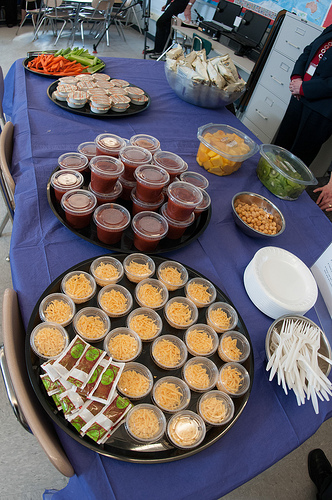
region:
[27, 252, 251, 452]
cheese cups on a tray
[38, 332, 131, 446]
sauce packets on the tray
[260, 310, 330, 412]
forks in a bowl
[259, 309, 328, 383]
the bowl is metal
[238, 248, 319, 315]
a stack of styrofoam plates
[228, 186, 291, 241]
chickpeas in a bowl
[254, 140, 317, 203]
kiwi in a plastic dish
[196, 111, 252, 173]
mango in a plastic dish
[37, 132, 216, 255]
small dishes of sauce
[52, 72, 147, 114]
peanut butter cups on a tray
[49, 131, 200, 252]
Portable containers of salsa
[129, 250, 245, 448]
Portable containers of cheese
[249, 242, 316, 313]
Styrofoam plates for food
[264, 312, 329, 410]
Bowl of disposable forks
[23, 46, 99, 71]
Plate of carrots and celery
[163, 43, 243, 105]
Bags of unknown snacks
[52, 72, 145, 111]
Dip to be used with veggies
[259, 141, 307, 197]
Container of Kiwi fruit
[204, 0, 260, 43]
Two computers with keyboards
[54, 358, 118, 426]
Packets of unknown condiments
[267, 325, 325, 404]
plastic forks are in a bowl.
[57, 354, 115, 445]
Packets of sauce are on a tray.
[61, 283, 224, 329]
Shredded cheese are on a tray.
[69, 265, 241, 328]
A tray of shredded cheese is on a table.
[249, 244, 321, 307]
styrofoam plates are stacked on a table.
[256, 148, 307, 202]
A container of kiwi is on a table.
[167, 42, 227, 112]
bags are stacked in a bowl.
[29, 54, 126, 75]
Veggies are served on a plate.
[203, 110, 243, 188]
container of pineapple is on the table.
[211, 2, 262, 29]
Headphones are hanging on a monitor.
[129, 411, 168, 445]
Shredded cheese in container.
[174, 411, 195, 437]
Orange shredded cheese in container.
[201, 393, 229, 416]
Orange shredded cheese in container.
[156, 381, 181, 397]
Orange shredded cheese in container.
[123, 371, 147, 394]
Orange shredded cheese in container.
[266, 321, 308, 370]
Plastic fork in silver bowl.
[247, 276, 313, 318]
Small white plates on table.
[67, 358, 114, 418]
Sauce packets on tray.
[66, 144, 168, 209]
Red sauce in containers.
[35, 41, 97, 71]
Carrots and celery in pile on tray.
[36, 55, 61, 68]
Stack of crisp carrots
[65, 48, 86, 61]
Stack of celery sticks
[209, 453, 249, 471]
Part of blue table cover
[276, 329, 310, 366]
Stack of white plastic forks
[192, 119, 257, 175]
Container of cheese cubes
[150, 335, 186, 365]
Container of shredded cheese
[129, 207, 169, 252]
Container of salsa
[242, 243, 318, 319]
Stack of white serving plates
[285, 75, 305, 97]
hands of person watching snacks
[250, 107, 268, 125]
Handle of filing cabinet drawer